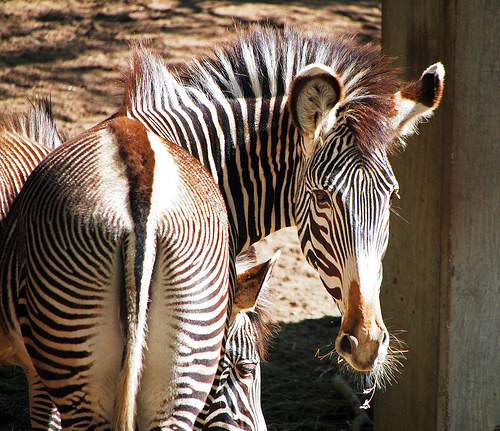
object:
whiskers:
[387, 332, 404, 349]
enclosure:
[393, 183, 470, 316]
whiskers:
[387, 350, 409, 354]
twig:
[361, 384, 377, 395]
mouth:
[332, 357, 387, 411]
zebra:
[3, 21, 448, 427]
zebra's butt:
[39, 207, 122, 381]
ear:
[387, 62, 445, 146]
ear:
[288, 62, 342, 140]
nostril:
[379, 331, 390, 349]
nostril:
[337, 335, 353, 357]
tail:
[113, 230, 161, 430]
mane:
[119, 28, 408, 162]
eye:
[311, 187, 332, 206]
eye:
[386, 190, 404, 208]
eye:
[235, 365, 257, 378]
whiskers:
[383, 373, 394, 388]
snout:
[334, 321, 390, 372]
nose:
[335, 330, 390, 358]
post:
[435, 6, 453, 429]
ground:
[8, 3, 393, 428]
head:
[288, 61, 447, 372]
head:
[195, 250, 282, 430]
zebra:
[1, 92, 283, 431]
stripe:
[106, 114, 158, 327]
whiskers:
[386, 355, 405, 367]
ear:
[232, 244, 289, 312]